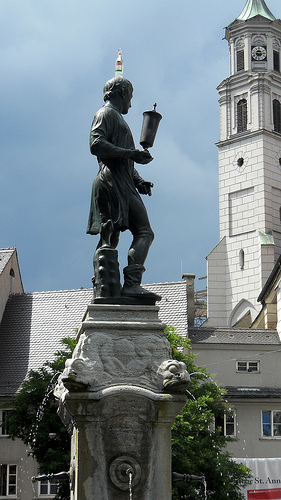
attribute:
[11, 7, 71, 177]
sky — blue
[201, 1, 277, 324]
tower — large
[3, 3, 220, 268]
sky — blue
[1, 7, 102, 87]
clouds — white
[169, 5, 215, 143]
clouds — white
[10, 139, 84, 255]
clouds — white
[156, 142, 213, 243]
clouds — white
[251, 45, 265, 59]
clock — tall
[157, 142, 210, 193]
clouds — white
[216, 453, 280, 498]
banner — white, red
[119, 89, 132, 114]
face — lizard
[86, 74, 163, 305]
statue — gray, dark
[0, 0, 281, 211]
clouds — white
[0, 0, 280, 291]
clouds — white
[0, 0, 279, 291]
sky — blue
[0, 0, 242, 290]
clouds — white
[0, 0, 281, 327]
sky — blue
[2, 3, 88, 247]
sky — blue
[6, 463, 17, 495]
window frame — white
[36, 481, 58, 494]
window frame — white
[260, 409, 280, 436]
window frame — white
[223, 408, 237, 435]
window frame — white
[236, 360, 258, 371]
window frame — white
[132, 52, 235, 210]
cloud — white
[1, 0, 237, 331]
sky — blue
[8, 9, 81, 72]
clouds — white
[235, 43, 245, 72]
window — small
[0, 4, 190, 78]
clouds — white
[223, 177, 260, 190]
blocks — white